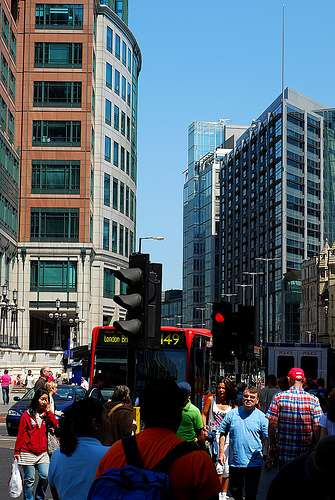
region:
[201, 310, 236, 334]
Red light is shining on the stop light.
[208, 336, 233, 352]
The stoplight is black.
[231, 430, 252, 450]
Man wearing a blue shirt.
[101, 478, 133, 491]
Man wearing a backpack.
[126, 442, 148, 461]
The straps are black.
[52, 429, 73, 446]
Woman with a pony tail.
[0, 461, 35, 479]
Woman carrying a bag.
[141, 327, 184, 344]
149 is written on the bus.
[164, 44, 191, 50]
The sky is blue.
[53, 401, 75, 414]
The car is blue.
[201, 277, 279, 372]
black street light with red light lit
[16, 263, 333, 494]
crowded city street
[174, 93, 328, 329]
tall city office buildings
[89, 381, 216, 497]
man wearing blue and black backpack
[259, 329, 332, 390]
police van parked on street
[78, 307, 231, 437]
red bus stopped in street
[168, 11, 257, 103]
clear blue skies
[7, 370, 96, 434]
blue car waiting at stop light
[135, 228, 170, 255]
tall modern street light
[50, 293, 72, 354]
short old fashioned street light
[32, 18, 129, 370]
Large building with many windows.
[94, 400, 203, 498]
Man wearing a blue backpack.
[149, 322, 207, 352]
Bus number 149 on front of bus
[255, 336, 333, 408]
Back of police vehicle with double doors.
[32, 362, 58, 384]
Bald man wearing glasses.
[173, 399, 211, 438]
Bright green polo type shirt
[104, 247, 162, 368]
Black traffic light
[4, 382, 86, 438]
Blue vehicle.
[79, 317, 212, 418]
Red and black bus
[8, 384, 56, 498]
Woman carrying a bag.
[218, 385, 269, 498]
man in blue shirt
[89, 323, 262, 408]
red bus with yellow writing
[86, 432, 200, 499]
blue backpack with black straps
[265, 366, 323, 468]
man in a red, white, and blue shirt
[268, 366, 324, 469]
man with a red hat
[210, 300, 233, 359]
a red traffic light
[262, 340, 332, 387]
vehicle says police in red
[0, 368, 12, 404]
woman in pink shirt and blue jeans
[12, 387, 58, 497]
woman in a red jacket with black hair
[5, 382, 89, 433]
car on a busy street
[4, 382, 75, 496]
Woman wearing red jacket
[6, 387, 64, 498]
Woman carry a white bag in right hand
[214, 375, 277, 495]
Man wearing blue t-shirt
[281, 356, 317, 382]
Red cap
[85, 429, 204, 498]
Blue backpack with black straps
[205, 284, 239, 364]
Traffic light is in red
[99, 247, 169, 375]
Traffic light in the street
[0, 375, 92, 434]
Blue car next to a bus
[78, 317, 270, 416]
Red bus on right side of street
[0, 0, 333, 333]
Tall buildings in the city